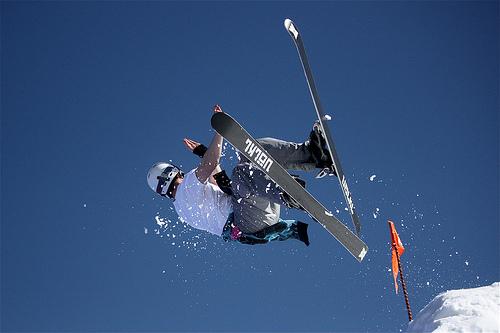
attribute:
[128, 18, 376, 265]
skier — jumping, black, airborn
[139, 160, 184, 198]
helmet — silver, white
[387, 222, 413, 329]
flag — orange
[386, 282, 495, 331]
snow — white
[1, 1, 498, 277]
sky — blue, clear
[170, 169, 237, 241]
shirt — white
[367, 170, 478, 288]
snow — flying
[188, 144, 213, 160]
gloves — black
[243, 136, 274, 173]
lettering — white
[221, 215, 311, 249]
jacket — blue, grey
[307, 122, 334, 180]
boot — black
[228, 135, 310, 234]
pants — grey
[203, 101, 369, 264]
ski — black